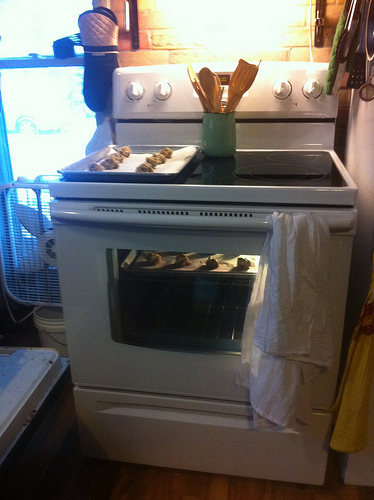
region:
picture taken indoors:
[22, 21, 370, 481]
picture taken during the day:
[10, 11, 362, 482]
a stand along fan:
[4, 167, 65, 323]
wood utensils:
[184, 46, 259, 144]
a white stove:
[63, 62, 354, 495]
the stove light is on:
[228, 251, 260, 274]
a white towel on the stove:
[255, 228, 324, 431]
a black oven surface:
[265, 156, 302, 177]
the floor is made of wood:
[70, 465, 121, 476]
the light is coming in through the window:
[10, 82, 70, 148]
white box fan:
[1, 173, 62, 307]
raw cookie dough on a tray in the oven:
[119, 247, 261, 279]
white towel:
[235, 209, 337, 431]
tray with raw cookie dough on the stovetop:
[56, 143, 203, 180]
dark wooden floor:
[0, 363, 373, 497]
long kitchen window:
[1, 0, 99, 238]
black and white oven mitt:
[76, 6, 121, 110]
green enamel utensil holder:
[199, 108, 238, 159]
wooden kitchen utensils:
[185, 58, 265, 114]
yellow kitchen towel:
[328, 272, 373, 453]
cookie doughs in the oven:
[119, 244, 258, 300]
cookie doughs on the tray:
[94, 143, 204, 192]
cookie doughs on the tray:
[82, 135, 189, 177]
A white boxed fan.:
[4, 174, 70, 310]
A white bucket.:
[33, 308, 70, 359]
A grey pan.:
[119, 248, 264, 277]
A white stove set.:
[47, 63, 357, 490]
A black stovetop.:
[59, 136, 350, 188]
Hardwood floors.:
[4, 329, 371, 498]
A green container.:
[201, 112, 236, 157]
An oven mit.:
[78, 6, 120, 112]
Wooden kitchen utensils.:
[185, 50, 261, 119]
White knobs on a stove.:
[127, 81, 325, 100]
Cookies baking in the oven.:
[124, 247, 260, 276]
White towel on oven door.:
[237, 214, 324, 437]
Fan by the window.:
[0, 173, 64, 309]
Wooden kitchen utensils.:
[180, 59, 259, 113]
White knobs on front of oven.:
[122, 75, 176, 102]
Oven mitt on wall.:
[78, 6, 123, 111]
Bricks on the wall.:
[108, 0, 350, 61]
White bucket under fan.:
[30, 303, 68, 362]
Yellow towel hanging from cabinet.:
[330, 322, 372, 453]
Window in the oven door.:
[105, 242, 269, 357]